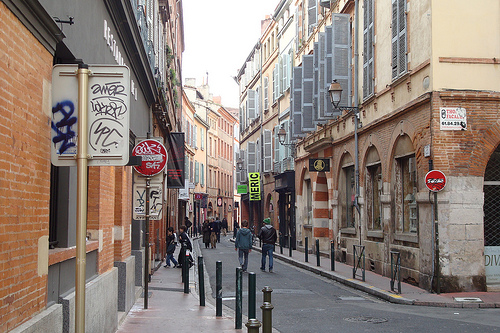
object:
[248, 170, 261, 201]
sign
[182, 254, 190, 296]
post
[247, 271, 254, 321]
post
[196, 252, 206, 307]
pole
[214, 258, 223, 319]
pole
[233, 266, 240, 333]
pole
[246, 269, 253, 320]
pole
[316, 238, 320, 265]
post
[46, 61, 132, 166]
graffiti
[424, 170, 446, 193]
caution sign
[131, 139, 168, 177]
caution sign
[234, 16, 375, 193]
windows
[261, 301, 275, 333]
poles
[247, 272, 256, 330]
green post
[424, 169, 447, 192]
sign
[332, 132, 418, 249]
arched windows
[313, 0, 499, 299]
building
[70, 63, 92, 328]
pole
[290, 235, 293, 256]
post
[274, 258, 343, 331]
pavement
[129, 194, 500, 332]
sidewalk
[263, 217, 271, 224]
hat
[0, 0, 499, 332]
buildings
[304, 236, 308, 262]
post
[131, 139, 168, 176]
sign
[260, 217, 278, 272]
men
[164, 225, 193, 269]
people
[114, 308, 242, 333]
pavement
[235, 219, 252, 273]
males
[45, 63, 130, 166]
sign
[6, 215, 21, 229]
brick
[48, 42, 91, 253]
windows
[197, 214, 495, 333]
street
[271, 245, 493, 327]
curb